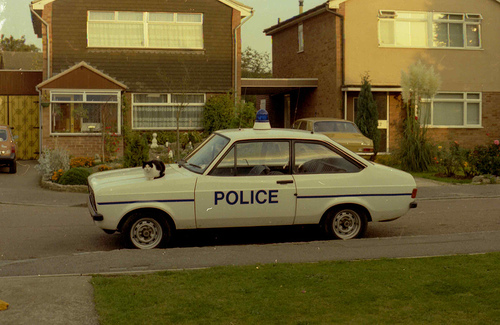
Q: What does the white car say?
A: Police.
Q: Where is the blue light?
A: On car roof.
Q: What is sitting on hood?
A: Cat.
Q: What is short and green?
A: Grass.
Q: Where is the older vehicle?
A: Parked on street.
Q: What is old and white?
A: Police car.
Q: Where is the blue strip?
A: On car.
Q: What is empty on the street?
A: Police car.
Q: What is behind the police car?
A: Houses.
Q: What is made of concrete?
A: Sidewlak.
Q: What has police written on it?
A: Car.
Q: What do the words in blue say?
A: Police.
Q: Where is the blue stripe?
A: On the car.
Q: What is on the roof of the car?
A: Blue blight.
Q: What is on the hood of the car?
A: A cat.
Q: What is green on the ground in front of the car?
A: Grass.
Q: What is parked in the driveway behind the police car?
A: A car.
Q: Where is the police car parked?
A: The street.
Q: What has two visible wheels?
A: The police car.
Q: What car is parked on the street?
A: A white car.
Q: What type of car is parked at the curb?
A: A police car.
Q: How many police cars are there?
A: One.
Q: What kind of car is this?
A: A police car.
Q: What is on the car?
A: A cat.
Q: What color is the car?
A: White.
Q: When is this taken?
A: During the day.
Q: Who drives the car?
A: Cops.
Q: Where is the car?
A: Parked on the road.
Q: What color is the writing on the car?
A: Black.